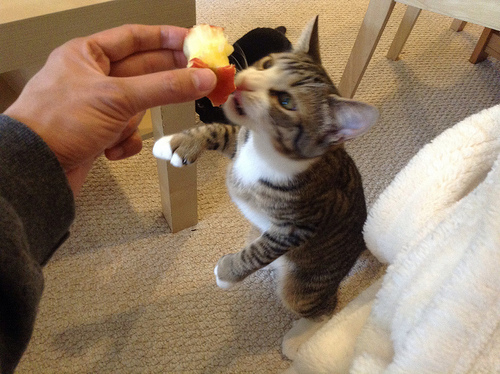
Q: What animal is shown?
A: A cat.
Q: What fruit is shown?
A: Apple.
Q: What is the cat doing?
A: Sniffing an apple.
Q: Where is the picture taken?
A: A living room.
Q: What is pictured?
A: Animal.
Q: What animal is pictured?
A: Cat.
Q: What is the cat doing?
A: Eating.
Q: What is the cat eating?
A: Apple.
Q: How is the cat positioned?
A: On the two hind legs.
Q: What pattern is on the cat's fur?
A: Stripes.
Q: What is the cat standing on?
A: Carpet.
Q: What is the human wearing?
A: Sweatshirt.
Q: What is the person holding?
A: Apple core.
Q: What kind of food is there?
A: Apple.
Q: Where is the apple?
A: In the person's hand.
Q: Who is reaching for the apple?
A: A kitten.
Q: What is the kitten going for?
A: The apple.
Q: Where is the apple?
A: In a man's hand.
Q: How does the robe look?
A: Fuzzy.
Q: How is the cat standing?
A: On his hind legs.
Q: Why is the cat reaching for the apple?
A: To eat it.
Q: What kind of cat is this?
A: Tabby.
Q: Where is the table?
A: Behind the cat.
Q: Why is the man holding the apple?
A: For the cat to sniff.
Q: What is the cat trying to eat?
A: An Apple.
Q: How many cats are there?
A: One.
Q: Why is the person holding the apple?
A: To feed the cat.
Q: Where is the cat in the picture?
A: In the center.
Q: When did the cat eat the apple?
A: Now.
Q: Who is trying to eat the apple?
A: The cat.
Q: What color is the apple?
A: Red.